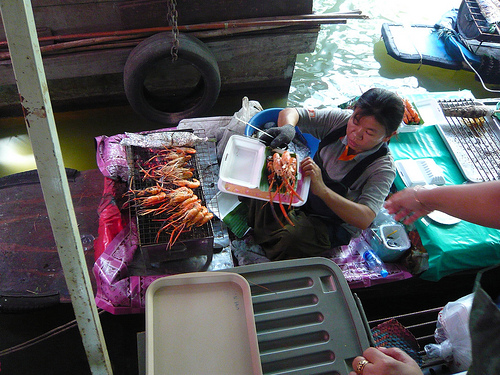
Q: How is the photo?
A: Clear.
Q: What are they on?
A: Boat.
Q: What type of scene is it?
A: Outdoor.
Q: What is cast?
A: Reflection.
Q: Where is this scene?
A: Waterbody.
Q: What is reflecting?
A: Water.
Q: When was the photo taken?
A: Daytime.